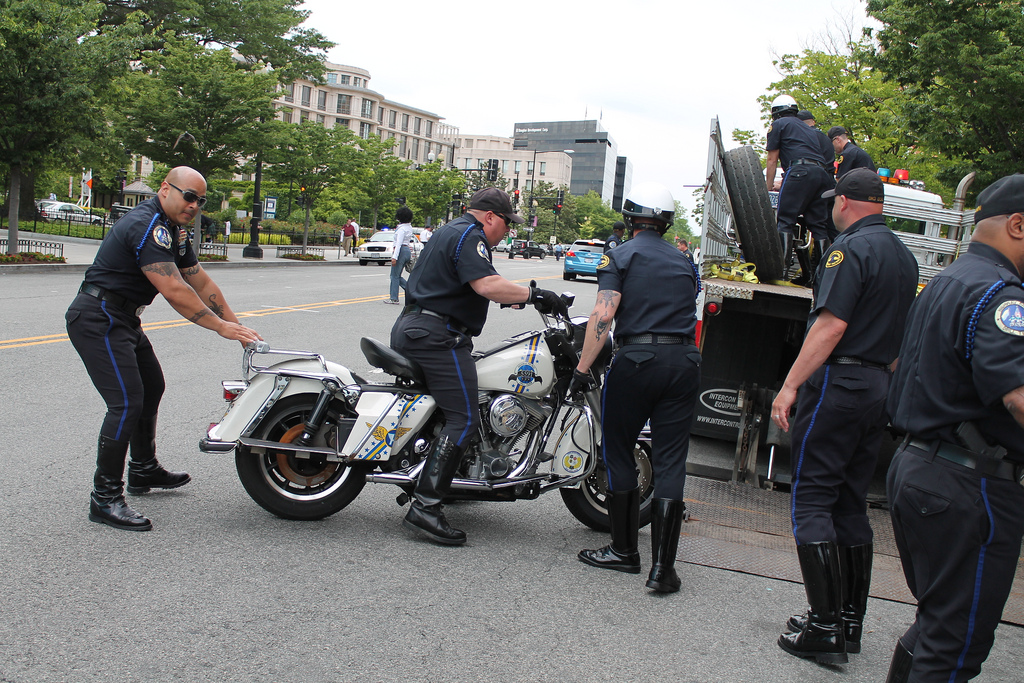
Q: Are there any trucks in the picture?
A: Yes, there is a truck.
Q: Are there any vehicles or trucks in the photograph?
A: Yes, there is a truck.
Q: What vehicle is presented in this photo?
A: The vehicle is a truck.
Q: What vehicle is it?
A: The vehicle is a truck.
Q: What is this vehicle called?
A: That is a truck.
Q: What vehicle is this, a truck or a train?
A: That is a truck.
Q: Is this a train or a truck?
A: This is a truck.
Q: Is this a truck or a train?
A: This is a truck.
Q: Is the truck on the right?
A: Yes, the truck is on the right of the image.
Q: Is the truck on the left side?
A: No, the truck is on the right of the image.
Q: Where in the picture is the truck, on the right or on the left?
A: The truck is on the right of the image.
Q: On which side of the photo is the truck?
A: The truck is on the right of the image.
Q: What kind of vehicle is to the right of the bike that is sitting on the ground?
A: The vehicle is a truck.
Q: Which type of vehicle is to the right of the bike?
A: The vehicle is a truck.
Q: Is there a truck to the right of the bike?
A: Yes, there is a truck to the right of the bike.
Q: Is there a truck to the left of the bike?
A: No, the truck is to the right of the bike.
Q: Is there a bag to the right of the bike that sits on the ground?
A: No, there is a truck to the right of the bike.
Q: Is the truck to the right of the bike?
A: Yes, the truck is to the right of the bike.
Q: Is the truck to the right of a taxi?
A: No, the truck is to the right of the bike.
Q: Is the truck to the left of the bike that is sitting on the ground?
A: No, the truck is to the right of the bike.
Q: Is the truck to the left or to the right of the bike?
A: The truck is to the right of the bike.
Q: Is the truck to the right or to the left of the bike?
A: The truck is to the right of the bike.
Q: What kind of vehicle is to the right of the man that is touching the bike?
A: The vehicle is a truck.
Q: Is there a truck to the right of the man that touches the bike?
A: Yes, there is a truck to the right of the man.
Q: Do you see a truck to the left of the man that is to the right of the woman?
A: No, the truck is to the right of the man.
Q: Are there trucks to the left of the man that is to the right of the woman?
A: No, the truck is to the right of the man.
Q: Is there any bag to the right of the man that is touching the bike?
A: No, there is a truck to the right of the man.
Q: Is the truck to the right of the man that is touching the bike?
A: Yes, the truck is to the right of the man.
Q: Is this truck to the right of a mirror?
A: No, the truck is to the right of the man.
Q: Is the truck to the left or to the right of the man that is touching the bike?
A: The truck is to the right of the man.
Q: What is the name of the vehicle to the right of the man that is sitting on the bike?
A: The vehicle is a truck.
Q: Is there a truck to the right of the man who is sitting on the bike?
A: Yes, there is a truck to the right of the man.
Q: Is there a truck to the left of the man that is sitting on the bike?
A: No, the truck is to the right of the man.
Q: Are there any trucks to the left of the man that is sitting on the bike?
A: No, the truck is to the right of the man.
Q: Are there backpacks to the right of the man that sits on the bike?
A: No, there is a truck to the right of the man.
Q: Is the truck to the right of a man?
A: Yes, the truck is to the right of a man.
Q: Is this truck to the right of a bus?
A: No, the truck is to the right of a man.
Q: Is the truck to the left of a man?
A: No, the truck is to the right of a man.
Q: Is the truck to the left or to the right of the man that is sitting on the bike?
A: The truck is to the right of the man.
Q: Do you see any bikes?
A: Yes, there is a bike.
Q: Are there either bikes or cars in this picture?
A: Yes, there is a bike.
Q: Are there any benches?
A: No, there are no benches.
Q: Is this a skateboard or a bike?
A: This is a bike.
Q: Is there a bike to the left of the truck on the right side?
A: Yes, there is a bike to the left of the truck.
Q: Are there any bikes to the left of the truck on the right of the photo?
A: Yes, there is a bike to the left of the truck.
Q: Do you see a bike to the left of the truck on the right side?
A: Yes, there is a bike to the left of the truck.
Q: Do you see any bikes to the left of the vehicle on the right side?
A: Yes, there is a bike to the left of the truck.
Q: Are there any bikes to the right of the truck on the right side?
A: No, the bike is to the left of the truck.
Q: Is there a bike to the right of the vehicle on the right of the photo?
A: No, the bike is to the left of the truck.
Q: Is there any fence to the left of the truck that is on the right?
A: No, there is a bike to the left of the truck.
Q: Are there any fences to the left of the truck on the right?
A: No, there is a bike to the left of the truck.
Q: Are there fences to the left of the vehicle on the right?
A: No, there is a bike to the left of the truck.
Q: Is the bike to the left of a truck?
A: Yes, the bike is to the left of a truck.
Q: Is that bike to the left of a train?
A: No, the bike is to the left of a truck.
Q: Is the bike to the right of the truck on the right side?
A: No, the bike is to the left of the truck.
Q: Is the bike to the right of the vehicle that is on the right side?
A: No, the bike is to the left of the truck.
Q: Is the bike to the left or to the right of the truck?
A: The bike is to the left of the truck.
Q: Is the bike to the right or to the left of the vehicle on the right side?
A: The bike is to the left of the truck.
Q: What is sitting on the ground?
A: The bike is sitting on the ground.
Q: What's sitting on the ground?
A: The bike is sitting on the ground.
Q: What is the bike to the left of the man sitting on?
A: The bike is sitting on the ground.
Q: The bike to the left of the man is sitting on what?
A: The bike is sitting on the ground.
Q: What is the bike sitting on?
A: The bike is sitting on the ground.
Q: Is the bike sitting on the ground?
A: Yes, the bike is sitting on the ground.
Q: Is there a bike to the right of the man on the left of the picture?
A: Yes, there is a bike to the right of the man.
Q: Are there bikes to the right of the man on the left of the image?
A: Yes, there is a bike to the right of the man.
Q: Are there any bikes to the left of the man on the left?
A: No, the bike is to the right of the man.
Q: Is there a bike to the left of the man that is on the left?
A: No, the bike is to the right of the man.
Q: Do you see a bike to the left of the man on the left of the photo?
A: No, the bike is to the right of the man.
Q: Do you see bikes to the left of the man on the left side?
A: No, the bike is to the right of the man.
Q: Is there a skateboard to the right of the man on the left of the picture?
A: No, there is a bike to the right of the man.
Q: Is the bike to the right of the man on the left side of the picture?
A: Yes, the bike is to the right of the man.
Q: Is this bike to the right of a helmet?
A: No, the bike is to the right of the man.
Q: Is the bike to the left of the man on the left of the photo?
A: No, the bike is to the right of the man.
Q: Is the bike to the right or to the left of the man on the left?
A: The bike is to the right of the man.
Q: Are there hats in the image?
A: Yes, there is a hat.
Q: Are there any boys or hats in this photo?
A: Yes, there is a hat.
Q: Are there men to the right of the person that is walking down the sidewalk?
A: Yes, there is a man to the right of the person.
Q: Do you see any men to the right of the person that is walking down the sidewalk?
A: Yes, there is a man to the right of the person.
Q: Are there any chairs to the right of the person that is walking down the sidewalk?
A: No, there is a man to the right of the person.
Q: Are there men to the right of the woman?
A: Yes, there is a man to the right of the woman.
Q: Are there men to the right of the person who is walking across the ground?
A: Yes, there is a man to the right of the woman.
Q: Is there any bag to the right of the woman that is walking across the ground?
A: No, there is a man to the right of the woman.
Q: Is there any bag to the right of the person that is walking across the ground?
A: No, there is a man to the right of the woman.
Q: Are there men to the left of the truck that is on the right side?
A: Yes, there is a man to the left of the truck.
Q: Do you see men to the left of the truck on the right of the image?
A: Yes, there is a man to the left of the truck.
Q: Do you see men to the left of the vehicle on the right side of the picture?
A: Yes, there is a man to the left of the truck.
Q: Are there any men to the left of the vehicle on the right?
A: Yes, there is a man to the left of the truck.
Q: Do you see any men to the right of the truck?
A: No, the man is to the left of the truck.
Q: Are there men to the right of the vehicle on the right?
A: No, the man is to the left of the truck.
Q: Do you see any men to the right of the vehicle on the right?
A: No, the man is to the left of the truck.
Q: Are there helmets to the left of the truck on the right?
A: No, there is a man to the left of the truck.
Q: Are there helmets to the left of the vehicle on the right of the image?
A: No, there is a man to the left of the truck.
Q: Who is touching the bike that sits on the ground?
A: The man is touching the bike.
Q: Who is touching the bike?
A: The man is touching the bike.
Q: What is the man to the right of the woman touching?
A: The man is touching the bike.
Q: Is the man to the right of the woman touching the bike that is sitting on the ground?
A: Yes, the man is touching the bike.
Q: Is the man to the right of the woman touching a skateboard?
A: No, the man is touching the bike.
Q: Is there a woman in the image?
A: Yes, there is a woman.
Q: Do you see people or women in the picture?
A: Yes, there is a woman.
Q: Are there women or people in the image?
A: Yes, there is a woman.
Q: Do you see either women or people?
A: Yes, there is a woman.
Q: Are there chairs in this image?
A: No, there are no chairs.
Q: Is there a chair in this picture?
A: No, there are no chairs.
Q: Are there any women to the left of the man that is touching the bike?
A: Yes, there is a woman to the left of the man.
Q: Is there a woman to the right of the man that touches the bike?
A: No, the woman is to the left of the man.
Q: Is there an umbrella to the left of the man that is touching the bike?
A: No, there is a woman to the left of the man.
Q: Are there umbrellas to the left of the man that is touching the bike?
A: No, there is a woman to the left of the man.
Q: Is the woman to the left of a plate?
A: No, the woman is to the left of a man.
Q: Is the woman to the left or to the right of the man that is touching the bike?
A: The woman is to the left of the man.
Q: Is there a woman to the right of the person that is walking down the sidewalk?
A: Yes, there is a woman to the right of the person.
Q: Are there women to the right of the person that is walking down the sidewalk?
A: Yes, there is a woman to the right of the person.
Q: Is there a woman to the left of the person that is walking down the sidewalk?
A: No, the woman is to the right of the person.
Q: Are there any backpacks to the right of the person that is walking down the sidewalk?
A: No, there is a woman to the right of the person.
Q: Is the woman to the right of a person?
A: Yes, the woman is to the right of a person.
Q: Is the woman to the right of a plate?
A: No, the woman is to the right of a person.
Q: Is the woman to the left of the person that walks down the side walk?
A: No, the woman is to the right of the person.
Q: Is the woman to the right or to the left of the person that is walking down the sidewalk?
A: The woman is to the right of the person.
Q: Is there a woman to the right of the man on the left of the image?
A: Yes, there is a woman to the right of the man.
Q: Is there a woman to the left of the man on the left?
A: No, the woman is to the right of the man.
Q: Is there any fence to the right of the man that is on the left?
A: No, there is a woman to the right of the man.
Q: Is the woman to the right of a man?
A: Yes, the woman is to the right of a man.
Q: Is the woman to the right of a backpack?
A: No, the woman is to the right of a man.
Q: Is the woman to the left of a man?
A: No, the woman is to the right of a man.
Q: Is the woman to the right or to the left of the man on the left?
A: The woman is to the right of the man.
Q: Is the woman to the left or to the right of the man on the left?
A: The woman is to the right of the man.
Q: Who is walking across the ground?
A: The woman is walking across the ground.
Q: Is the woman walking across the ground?
A: Yes, the woman is walking across the ground.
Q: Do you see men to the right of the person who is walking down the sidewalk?
A: Yes, there is a man to the right of the person.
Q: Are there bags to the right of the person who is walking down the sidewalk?
A: No, there is a man to the right of the person.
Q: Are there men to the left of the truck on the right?
A: Yes, there is a man to the left of the truck.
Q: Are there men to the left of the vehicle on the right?
A: Yes, there is a man to the left of the truck.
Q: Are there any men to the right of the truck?
A: No, the man is to the left of the truck.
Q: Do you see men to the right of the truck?
A: No, the man is to the left of the truck.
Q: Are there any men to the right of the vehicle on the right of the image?
A: No, the man is to the left of the truck.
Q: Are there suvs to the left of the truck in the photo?
A: No, there is a man to the left of the truck.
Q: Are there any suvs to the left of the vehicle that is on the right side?
A: No, there is a man to the left of the truck.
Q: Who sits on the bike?
A: The man sits on the bike.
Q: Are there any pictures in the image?
A: No, there are no pictures.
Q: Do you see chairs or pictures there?
A: No, there are no pictures or chairs.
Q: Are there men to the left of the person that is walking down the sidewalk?
A: Yes, there is a man to the left of the person.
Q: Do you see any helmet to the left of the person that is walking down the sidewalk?
A: No, there is a man to the left of the person.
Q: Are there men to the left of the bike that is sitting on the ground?
A: Yes, there is a man to the left of the bike.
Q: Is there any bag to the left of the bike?
A: No, there is a man to the left of the bike.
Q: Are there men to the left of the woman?
A: Yes, there is a man to the left of the woman.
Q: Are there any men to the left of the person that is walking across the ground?
A: Yes, there is a man to the left of the woman.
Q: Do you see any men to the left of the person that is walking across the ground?
A: Yes, there is a man to the left of the woman.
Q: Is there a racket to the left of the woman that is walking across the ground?
A: No, there is a man to the left of the woman.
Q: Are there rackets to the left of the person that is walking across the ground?
A: No, there is a man to the left of the woman.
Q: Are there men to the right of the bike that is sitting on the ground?
A: Yes, there is a man to the right of the bike.